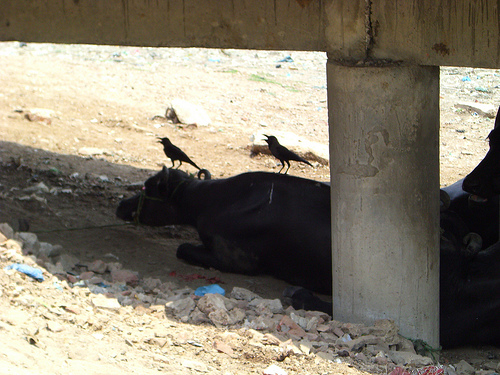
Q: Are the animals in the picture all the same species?
A: No, they are birds and cows.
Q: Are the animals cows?
A: No, there are both birds and cows.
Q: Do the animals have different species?
A: Yes, they are birds and cows.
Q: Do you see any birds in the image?
A: Yes, there is a bird.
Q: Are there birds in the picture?
A: Yes, there is a bird.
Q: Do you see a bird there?
A: Yes, there is a bird.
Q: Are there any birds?
A: Yes, there is a bird.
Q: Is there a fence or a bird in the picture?
A: Yes, there is a bird.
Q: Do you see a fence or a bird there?
A: Yes, there is a bird.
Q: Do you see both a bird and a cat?
A: No, there is a bird but no cats.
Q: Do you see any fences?
A: No, there are no fences.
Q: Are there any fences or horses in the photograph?
A: No, there are no fences or horses.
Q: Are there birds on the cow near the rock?
A: Yes, there is a bird on the cow.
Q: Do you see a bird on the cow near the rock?
A: Yes, there is a bird on the cow.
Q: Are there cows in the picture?
A: Yes, there is a cow.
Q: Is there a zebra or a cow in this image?
A: Yes, there is a cow.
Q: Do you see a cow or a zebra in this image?
A: Yes, there is a cow.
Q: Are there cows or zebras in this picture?
A: Yes, there is a cow.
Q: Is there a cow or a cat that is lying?
A: Yes, the cow is lying.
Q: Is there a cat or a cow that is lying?
A: Yes, the cow is lying.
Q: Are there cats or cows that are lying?
A: Yes, the cow is lying.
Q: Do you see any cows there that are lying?
A: Yes, there is a cow that is lying.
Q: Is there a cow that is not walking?
A: Yes, there is a cow that is lying.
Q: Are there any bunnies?
A: No, there are no bunnies.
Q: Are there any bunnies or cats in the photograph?
A: No, there are no bunnies or cats.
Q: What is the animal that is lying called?
A: The animal is a cow.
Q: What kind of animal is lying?
A: The animal is a cow.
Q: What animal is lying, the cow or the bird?
A: The cow is lying.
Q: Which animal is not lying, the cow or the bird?
A: The bird is not lying.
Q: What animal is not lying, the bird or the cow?
A: The bird is not lying.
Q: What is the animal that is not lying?
A: The animal is a bird.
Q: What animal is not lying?
A: The animal is a bird.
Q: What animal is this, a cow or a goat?
A: This is a cow.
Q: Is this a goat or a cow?
A: This is a cow.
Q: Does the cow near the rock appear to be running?
A: No, the cow is lying.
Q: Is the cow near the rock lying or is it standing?
A: The cow is lying.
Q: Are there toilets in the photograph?
A: No, there are no toilets.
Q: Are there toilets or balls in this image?
A: No, there are no toilets or balls.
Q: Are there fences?
A: No, there are no fences.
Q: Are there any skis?
A: No, there are no skis.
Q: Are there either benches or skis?
A: No, there are no skis or benches.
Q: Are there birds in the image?
A: Yes, there is a bird.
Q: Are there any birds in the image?
A: Yes, there is a bird.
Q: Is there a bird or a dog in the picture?
A: Yes, there is a bird.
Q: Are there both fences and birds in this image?
A: No, there is a bird but no fences.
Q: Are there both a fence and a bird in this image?
A: No, there is a bird but no fences.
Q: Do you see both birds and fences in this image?
A: No, there is a bird but no fences.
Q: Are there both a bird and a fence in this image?
A: No, there is a bird but no fences.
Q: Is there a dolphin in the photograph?
A: No, there are no dolphins.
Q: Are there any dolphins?
A: No, there are no dolphins.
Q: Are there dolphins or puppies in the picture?
A: No, there are no dolphins or puppies.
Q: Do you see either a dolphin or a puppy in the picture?
A: No, there are no dolphins or puppies.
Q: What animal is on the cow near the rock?
A: The bird is on the cow.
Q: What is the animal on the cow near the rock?
A: The animal is a bird.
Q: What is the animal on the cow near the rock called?
A: The animal is a bird.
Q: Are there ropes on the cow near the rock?
A: No, there is a bird on the cow.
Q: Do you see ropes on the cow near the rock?
A: No, there is a bird on the cow.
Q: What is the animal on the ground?
A: The animal is a bird.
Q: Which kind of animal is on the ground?
A: The animal is a bird.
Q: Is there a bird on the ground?
A: Yes, there is a bird on the ground.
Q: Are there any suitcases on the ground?
A: No, there is a bird on the ground.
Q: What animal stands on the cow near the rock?
A: The bird stands on the cow.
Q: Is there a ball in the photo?
A: No, there are no balls.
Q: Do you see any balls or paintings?
A: No, there are no balls or paintings.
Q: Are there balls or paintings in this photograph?
A: No, there are no balls or paintings.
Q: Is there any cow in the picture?
A: Yes, there is a cow.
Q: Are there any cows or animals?
A: Yes, there is a cow.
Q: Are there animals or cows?
A: Yes, there is a cow.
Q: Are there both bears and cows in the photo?
A: No, there is a cow but no bears.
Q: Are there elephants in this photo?
A: No, there are no elephants.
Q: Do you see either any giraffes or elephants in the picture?
A: No, there are no elephants or giraffes.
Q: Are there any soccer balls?
A: No, there are no soccer balls.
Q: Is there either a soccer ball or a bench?
A: No, there are no soccer balls or benches.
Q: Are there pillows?
A: No, there are no pillows.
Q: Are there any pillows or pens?
A: No, there are no pillows or pens.